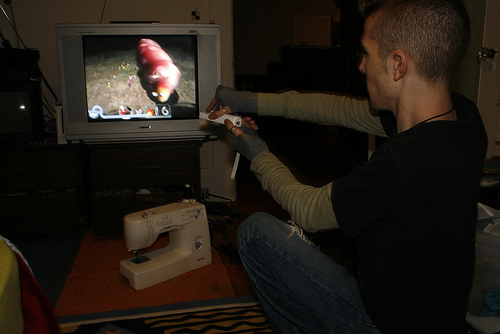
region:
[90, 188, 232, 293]
A white sewing machine.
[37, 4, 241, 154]
A silver tv turned on.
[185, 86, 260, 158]
A white wii control.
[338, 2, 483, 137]
Man with very short haircut.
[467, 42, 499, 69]
A silver door knob.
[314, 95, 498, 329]
A black tee shirt.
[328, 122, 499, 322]
A short sleeve tee shirt.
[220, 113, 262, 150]
A ring on left thumb.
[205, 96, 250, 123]
A ring on right thumb.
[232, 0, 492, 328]
Man wearing a pair of jeans.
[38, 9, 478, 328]
playing video games while sewing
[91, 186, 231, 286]
a sewing machine in front of a TV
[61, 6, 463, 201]
a gamer involved in the action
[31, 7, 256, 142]
the television is against the wall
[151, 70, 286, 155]
the control manipulates the game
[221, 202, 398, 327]
this gamer is wearing geans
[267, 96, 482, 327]
the gamer's shirt is black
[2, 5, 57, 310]
looks like a computer in the background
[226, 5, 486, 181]
a darks section of the gamer's home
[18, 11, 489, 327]
this area looks congested and cluttered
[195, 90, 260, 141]
white Wii remote control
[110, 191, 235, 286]
white sowing machine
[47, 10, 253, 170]
video game on tv screen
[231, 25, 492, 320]
guy playing video games on TV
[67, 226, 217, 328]
red rug under sewing machine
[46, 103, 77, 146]
wii console next to TV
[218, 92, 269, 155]
rings on man's thumbs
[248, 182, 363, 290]
man wearing ripped jeans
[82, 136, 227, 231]
black TV stand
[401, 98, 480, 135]
black necklace on man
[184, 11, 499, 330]
a man wearing a black shirt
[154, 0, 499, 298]
a man playing the wii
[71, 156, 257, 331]
a white sewing machine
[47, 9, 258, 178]
a television turned on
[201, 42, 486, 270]
long sleeves under shirt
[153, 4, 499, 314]
a man with shirt hair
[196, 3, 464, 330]
a man sitting down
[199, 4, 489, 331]
a man wearing jeans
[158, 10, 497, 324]
a man inside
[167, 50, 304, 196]
a white wii remote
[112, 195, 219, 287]
Sewing machine on a red blanket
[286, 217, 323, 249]
Rip in a man's jeans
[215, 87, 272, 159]
Man wearing gray gloves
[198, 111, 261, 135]
Man holding a white wii mote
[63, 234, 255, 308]
Red rug on the floor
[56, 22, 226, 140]
Grey TV against a wall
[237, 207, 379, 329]
Man in jeans crouched down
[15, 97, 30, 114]
Light reflecting on a black surface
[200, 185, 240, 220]
Cords plugged in to the wall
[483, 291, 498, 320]
Teal colored rag in the corner